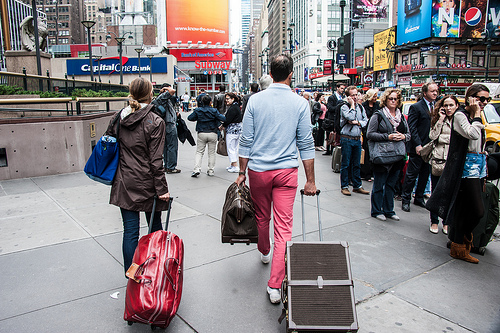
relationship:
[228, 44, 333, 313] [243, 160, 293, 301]
man with pink pants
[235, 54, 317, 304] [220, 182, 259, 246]
man with luggage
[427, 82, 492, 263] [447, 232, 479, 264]
woman with boots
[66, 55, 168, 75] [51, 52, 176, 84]
sign on wall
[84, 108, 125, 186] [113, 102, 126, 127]
bag on shoulder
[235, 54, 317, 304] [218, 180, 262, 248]
man with suitcase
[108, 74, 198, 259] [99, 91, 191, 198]
lady with coat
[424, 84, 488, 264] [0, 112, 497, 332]
woman standing on a street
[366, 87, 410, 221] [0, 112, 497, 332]
person standing on a street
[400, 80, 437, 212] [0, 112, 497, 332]
person standing on a street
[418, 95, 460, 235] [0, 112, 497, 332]
women standing on a street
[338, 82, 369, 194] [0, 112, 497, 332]
person standing on a street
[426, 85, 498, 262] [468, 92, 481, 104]
women talking on cellphones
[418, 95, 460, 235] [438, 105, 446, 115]
women talking on cellphones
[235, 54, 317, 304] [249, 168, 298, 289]
man wearing pink pants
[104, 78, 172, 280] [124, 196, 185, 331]
lady pulling a suit case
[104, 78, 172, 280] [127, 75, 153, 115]
lady with hair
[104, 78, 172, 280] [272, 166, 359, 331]
lady pulling suitcase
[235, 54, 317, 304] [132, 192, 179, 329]
man pulling suitcase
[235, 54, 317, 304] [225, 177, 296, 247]
man carries a bag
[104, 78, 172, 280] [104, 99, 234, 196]
lady wearing jacket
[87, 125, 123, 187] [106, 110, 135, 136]
bag on shoulder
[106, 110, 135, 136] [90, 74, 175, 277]
shoulder of woman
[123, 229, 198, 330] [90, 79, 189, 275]
luggage behind woman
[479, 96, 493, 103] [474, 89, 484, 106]
glasses on face